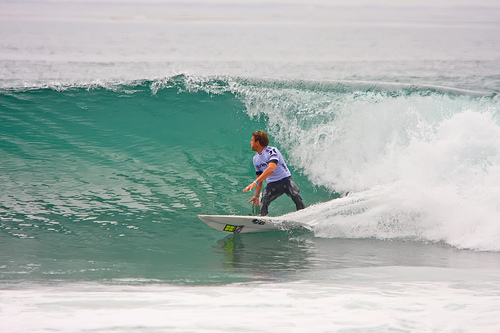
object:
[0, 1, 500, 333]
ocean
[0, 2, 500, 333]
photo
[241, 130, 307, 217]
surfer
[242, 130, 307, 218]
man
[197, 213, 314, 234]
surfboard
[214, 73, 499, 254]
wave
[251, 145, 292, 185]
shirt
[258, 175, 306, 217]
pants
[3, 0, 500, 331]
water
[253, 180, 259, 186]
watch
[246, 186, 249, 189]
ring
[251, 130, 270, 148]
hair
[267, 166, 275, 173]
elbow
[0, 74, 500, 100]
edge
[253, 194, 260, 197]
band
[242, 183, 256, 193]
hand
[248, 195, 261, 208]
hand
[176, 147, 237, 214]
ripples